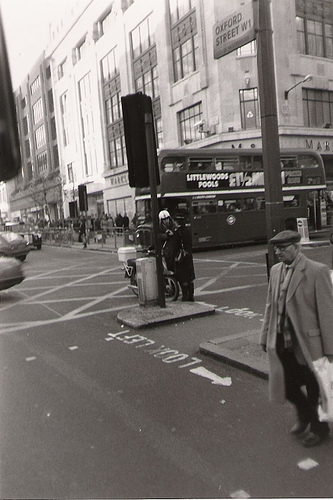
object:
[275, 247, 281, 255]
nose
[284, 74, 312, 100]
traffic lamp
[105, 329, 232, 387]
street print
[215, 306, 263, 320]
street print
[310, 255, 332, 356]
arms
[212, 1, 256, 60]
sign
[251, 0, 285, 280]
pole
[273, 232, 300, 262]
head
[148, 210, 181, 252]
man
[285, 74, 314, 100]
light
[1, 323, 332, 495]
street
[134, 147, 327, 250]
bus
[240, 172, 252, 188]
1/2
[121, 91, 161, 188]
light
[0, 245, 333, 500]
road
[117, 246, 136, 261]
container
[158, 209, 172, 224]
hat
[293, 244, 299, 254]
ear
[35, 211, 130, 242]
crowd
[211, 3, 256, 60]
signpost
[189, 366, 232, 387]
arrow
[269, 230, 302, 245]
hat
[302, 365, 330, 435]
legs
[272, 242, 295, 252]
glasses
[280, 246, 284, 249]
eyes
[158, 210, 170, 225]
helmet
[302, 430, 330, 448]
feet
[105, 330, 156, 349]
print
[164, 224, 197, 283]
coat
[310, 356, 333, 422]
bag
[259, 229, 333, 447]
man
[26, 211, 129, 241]
people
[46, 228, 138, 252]
sidewalk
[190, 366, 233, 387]
white print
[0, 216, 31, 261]
cars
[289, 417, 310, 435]
shoes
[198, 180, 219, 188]
text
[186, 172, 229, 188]
print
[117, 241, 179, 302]
motorcycle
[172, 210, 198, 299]
woman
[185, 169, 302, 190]
poster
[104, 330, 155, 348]
word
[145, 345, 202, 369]
word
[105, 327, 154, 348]
left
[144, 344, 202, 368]
look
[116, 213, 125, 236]
person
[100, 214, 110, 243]
person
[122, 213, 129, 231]
person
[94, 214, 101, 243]
person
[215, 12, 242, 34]
oxford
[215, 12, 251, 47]
street w1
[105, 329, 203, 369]
letter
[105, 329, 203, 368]
look left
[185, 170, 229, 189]
littlewoods pools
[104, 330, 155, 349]
mark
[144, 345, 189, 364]
mark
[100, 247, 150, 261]
corner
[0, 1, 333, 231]
building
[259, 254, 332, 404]
coat